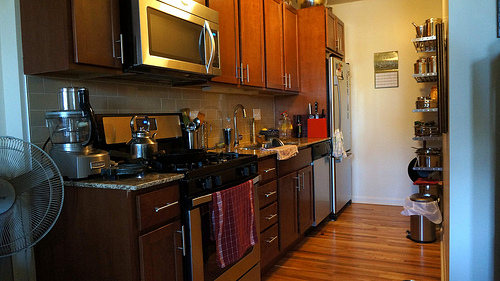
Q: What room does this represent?
A: It represents the kitchen.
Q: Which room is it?
A: It is a kitchen.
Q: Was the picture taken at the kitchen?
A: Yes, it was taken in the kitchen.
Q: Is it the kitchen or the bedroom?
A: It is the kitchen.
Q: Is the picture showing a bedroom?
A: No, the picture is showing a kitchen.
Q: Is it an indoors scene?
A: Yes, it is indoors.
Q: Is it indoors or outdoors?
A: It is indoors.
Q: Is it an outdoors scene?
A: No, it is indoors.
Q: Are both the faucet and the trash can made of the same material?
A: Yes, both the faucet and the trash can are made of metal.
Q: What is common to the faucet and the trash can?
A: The material, both the faucet and the trash can are metallic.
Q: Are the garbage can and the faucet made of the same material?
A: Yes, both the garbage can and the faucet are made of metal.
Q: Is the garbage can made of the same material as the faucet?
A: Yes, both the garbage can and the faucet are made of metal.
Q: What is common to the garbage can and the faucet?
A: The material, both the garbage can and the faucet are metallic.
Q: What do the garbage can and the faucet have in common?
A: The material, both the garbage can and the faucet are metallic.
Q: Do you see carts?
A: No, there are no carts.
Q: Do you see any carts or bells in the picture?
A: No, there are no carts or bells.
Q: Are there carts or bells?
A: No, there are no carts or bells.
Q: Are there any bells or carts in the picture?
A: No, there are no carts or bells.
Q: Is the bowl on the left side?
A: Yes, the bowl is on the left of the image.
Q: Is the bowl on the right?
A: No, the bowl is on the left of the image.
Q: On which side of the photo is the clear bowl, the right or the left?
A: The bowl is on the left of the image.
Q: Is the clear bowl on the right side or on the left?
A: The bowl is on the left of the image.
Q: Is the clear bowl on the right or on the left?
A: The bowl is on the left of the image.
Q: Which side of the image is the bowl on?
A: The bowl is on the left of the image.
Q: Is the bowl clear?
A: Yes, the bowl is clear.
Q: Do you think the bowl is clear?
A: Yes, the bowl is clear.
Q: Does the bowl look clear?
A: Yes, the bowl is clear.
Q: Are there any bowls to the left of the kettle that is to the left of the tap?
A: Yes, there is a bowl to the left of the kettle.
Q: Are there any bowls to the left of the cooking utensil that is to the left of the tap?
A: Yes, there is a bowl to the left of the kettle.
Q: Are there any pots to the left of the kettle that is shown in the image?
A: No, there is a bowl to the left of the kettle.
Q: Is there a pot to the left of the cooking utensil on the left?
A: No, there is a bowl to the left of the kettle.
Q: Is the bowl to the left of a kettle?
A: Yes, the bowl is to the left of a kettle.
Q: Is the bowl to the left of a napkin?
A: No, the bowl is to the left of a kettle.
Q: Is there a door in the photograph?
A: Yes, there is a door.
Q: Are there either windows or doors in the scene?
A: Yes, there is a door.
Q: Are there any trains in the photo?
A: No, there are no trains.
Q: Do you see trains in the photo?
A: No, there are no trains.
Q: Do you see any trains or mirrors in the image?
A: No, there are no trains or mirrors.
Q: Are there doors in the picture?
A: Yes, there is a door.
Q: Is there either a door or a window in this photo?
A: Yes, there is a door.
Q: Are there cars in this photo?
A: No, there are no cars.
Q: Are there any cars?
A: No, there are no cars.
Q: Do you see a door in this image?
A: Yes, there is a door.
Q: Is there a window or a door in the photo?
A: Yes, there is a door.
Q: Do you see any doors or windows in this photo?
A: Yes, there is a door.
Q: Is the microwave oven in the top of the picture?
A: Yes, the microwave oven is in the top of the image.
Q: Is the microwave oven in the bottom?
A: No, the microwave oven is in the top of the image.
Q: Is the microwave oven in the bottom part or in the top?
A: The microwave oven is in the top of the image.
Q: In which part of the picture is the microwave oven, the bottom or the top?
A: The microwave oven is in the top of the image.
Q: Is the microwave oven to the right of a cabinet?
A: Yes, the microwave oven is to the right of a cabinet.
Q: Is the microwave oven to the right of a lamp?
A: No, the microwave oven is to the right of a cabinet.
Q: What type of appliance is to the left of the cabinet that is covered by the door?
A: The appliance is a microwave oven.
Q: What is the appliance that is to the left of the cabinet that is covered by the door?
A: The appliance is a microwave oven.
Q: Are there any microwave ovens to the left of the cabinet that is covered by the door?
A: Yes, there is a microwave oven to the left of the cabinet.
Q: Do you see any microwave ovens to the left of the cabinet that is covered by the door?
A: Yes, there is a microwave oven to the left of the cabinet.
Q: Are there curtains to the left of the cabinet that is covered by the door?
A: No, there is a microwave oven to the left of the cabinet.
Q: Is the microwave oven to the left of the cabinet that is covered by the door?
A: Yes, the microwave oven is to the left of the cabinet.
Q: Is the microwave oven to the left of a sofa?
A: No, the microwave oven is to the left of the cabinet.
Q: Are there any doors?
A: Yes, there is a door.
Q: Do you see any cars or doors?
A: Yes, there is a door.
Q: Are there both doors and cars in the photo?
A: No, there is a door but no cars.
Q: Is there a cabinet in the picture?
A: Yes, there is a cabinet.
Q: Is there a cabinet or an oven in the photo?
A: Yes, there is a cabinet.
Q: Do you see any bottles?
A: No, there are no bottles.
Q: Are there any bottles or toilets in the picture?
A: No, there are no bottles or toilets.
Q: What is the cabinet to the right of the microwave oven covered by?
A: The cabinet is covered by the door.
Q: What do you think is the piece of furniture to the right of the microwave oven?
A: The piece of furniture is a cabinet.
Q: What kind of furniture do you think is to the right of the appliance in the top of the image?
A: The piece of furniture is a cabinet.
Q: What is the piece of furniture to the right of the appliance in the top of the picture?
A: The piece of furniture is a cabinet.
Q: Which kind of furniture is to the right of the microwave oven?
A: The piece of furniture is a cabinet.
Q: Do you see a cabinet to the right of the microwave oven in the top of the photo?
A: Yes, there is a cabinet to the right of the microwave oven.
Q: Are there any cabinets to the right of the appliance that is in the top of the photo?
A: Yes, there is a cabinet to the right of the microwave oven.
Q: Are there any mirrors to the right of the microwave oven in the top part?
A: No, there is a cabinet to the right of the microwave oven.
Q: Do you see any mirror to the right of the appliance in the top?
A: No, there is a cabinet to the right of the microwave oven.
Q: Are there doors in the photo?
A: Yes, there is a door.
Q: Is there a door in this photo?
A: Yes, there is a door.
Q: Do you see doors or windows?
A: Yes, there is a door.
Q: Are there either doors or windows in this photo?
A: Yes, there is a door.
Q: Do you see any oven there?
A: Yes, there is an oven.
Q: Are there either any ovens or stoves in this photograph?
A: Yes, there is an oven.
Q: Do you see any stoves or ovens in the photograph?
A: Yes, there is an oven.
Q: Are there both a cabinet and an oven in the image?
A: Yes, there are both an oven and a cabinet.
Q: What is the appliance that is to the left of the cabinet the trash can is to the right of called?
A: The appliance is an oven.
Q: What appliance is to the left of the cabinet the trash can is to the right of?
A: The appliance is an oven.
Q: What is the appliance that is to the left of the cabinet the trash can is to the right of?
A: The appliance is an oven.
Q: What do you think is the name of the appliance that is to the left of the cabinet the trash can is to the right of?
A: The appliance is an oven.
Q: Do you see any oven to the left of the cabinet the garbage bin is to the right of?
A: Yes, there is an oven to the left of the cabinet.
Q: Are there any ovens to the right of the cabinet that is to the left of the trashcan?
A: No, the oven is to the left of the cabinet.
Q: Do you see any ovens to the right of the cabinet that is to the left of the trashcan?
A: No, the oven is to the left of the cabinet.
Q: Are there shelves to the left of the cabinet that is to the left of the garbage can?
A: No, there is an oven to the left of the cabinet.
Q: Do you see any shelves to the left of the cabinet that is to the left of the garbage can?
A: No, there is an oven to the left of the cabinet.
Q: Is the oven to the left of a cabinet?
A: Yes, the oven is to the left of a cabinet.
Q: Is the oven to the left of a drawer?
A: No, the oven is to the left of a cabinet.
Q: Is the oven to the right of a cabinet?
A: No, the oven is to the left of a cabinet.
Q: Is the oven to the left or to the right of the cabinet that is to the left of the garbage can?
A: The oven is to the left of the cabinet.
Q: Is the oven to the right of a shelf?
A: No, the oven is to the right of a cabinet.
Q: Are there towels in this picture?
A: Yes, there is a towel.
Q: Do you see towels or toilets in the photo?
A: Yes, there is a towel.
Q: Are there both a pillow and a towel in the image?
A: No, there is a towel but no pillows.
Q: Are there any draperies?
A: No, there are no draperies.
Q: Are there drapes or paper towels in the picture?
A: No, there are no drapes or paper towels.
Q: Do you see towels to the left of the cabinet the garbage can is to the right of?
A: Yes, there is a towel to the left of the cabinet.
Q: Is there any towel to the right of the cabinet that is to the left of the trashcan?
A: No, the towel is to the left of the cabinet.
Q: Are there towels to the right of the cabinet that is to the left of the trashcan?
A: No, the towel is to the left of the cabinet.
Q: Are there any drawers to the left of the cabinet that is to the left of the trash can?
A: No, there is a towel to the left of the cabinet.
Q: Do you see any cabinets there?
A: Yes, there is a cabinet.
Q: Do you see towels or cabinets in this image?
A: Yes, there is a cabinet.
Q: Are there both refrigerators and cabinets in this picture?
A: Yes, there are both a cabinet and a refrigerator.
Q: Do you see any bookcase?
A: No, there are no bookcases.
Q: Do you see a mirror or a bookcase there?
A: No, there are no bookcases or mirrors.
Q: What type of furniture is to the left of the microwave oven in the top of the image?
A: The piece of furniture is a cabinet.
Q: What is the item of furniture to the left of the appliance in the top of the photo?
A: The piece of furniture is a cabinet.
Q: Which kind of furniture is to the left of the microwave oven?
A: The piece of furniture is a cabinet.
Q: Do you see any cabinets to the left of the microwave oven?
A: Yes, there is a cabinet to the left of the microwave oven.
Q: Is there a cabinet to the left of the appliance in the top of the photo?
A: Yes, there is a cabinet to the left of the microwave oven.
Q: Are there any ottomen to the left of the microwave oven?
A: No, there is a cabinet to the left of the microwave oven.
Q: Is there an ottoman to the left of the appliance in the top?
A: No, there is a cabinet to the left of the microwave oven.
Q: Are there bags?
A: Yes, there is a bag.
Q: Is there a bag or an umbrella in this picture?
A: Yes, there is a bag.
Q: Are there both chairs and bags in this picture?
A: No, there is a bag but no chairs.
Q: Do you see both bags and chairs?
A: No, there is a bag but no chairs.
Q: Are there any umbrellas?
A: No, there are no umbrellas.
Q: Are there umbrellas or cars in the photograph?
A: No, there are no umbrellas or cars.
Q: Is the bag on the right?
A: Yes, the bag is on the right of the image.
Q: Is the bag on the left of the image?
A: No, the bag is on the right of the image.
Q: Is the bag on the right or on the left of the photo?
A: The bag is on the right of the image.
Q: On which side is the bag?
A: The bag is on the right of the image.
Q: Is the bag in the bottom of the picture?
A: Yes, the bag is in the bottom of the image.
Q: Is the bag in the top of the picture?
A: No, the bag is in the bottom of the image.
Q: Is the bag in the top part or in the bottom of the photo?
A: The bag is in the bottom of the image.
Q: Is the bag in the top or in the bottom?
A: The bag is in the bottom of the image.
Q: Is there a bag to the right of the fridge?
A: Yes, there is a bag to the right of the fridge.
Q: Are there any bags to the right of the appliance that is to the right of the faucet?
A: Yes, there is a bag to the right of the fridge.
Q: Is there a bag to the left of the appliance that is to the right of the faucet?
A: No, the bag is to the right of the refrigerator.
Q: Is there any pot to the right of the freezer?
A: No, there is a bag to the right of the freezer.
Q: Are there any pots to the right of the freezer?
A: No, there is a bag to the right of the freezer.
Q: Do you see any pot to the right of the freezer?
A: No, there is a bag to the right of the freezer.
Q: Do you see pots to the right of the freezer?
A: No, there is a bag to the right of the freezer.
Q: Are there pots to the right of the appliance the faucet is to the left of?
A: No, there is a bag to the right of the freezer.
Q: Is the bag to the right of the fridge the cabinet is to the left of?
A: Yes, the bag is to the right of the freezer.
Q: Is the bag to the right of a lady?
A: No, the bag is to the right of the freezer.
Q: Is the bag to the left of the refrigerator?
A: No, the bag is to the right of the refrigerator.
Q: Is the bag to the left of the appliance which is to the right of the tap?
A: No, the bag is to the right of the refrigerator.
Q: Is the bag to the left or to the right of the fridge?
A: The bag is to the right of the fridge.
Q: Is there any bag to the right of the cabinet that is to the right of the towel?
A: Yes, there is a bag to the right of the cabinet.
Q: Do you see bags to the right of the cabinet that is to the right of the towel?
A: Yes, there is a bag to the right of the cabinet.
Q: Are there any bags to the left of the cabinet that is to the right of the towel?
A: No, the bag is to the right of the cabinet.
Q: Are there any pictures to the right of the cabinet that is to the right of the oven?
A: No, there is a bag to the right of the cabinet.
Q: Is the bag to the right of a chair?
A: No, the bag is to the right of a cabinet.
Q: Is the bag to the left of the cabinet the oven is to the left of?
A: No, the bag is to the right of the cabinet.